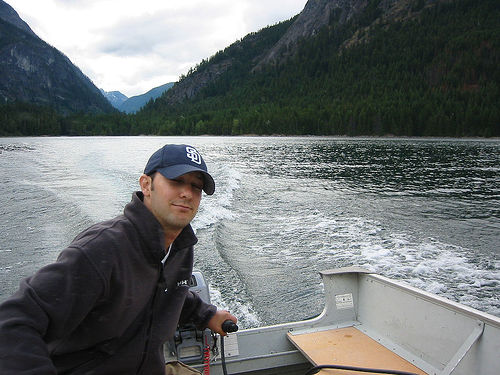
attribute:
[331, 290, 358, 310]
socket — white, electrical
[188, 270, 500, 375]
boat — white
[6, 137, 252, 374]
man — smiling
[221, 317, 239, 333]
object — black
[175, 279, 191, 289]
label — white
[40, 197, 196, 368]
jacket — man's, blue, large, grey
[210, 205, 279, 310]
waves — large, white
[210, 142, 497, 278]
water — calm, dark green, body, choppy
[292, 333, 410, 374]
bench — brown, wooden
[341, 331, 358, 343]
spot — small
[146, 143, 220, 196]
cap — dark blue, blue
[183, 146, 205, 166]
logo — white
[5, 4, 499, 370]
photo — clear, outdoors, daytime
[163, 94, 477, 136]
trees — green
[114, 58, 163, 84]
clouds — white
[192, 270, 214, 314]
engine — tan